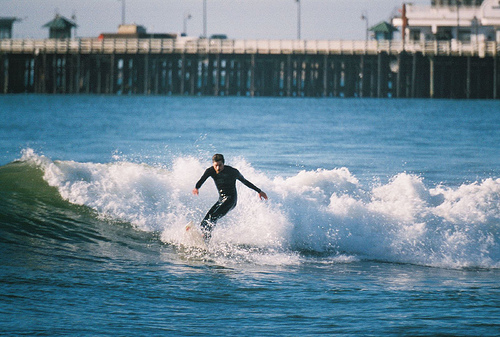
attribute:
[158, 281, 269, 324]
waves — white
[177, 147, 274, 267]
wet suit — black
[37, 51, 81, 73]
shelter — green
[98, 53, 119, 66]
clouds — white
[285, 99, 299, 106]
sky — blue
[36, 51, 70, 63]
sky — blue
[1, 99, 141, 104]
clouds — white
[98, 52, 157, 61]
clouds — white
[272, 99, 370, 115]
sky — blue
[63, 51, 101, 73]
sky — blue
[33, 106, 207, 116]
clouds — white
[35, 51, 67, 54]
clouds — white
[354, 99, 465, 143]
sky — blue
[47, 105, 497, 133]
fence — white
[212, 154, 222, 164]
hair — black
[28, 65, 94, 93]
clouds — white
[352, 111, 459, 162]
sky — black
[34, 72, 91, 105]
sky — blue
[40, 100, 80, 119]
clouds — white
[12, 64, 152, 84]
clouds — white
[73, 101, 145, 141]
sky — blue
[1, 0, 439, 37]
sky — blue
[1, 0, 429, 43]
clouds — white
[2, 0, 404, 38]
clouds — white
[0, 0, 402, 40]
sky — blue